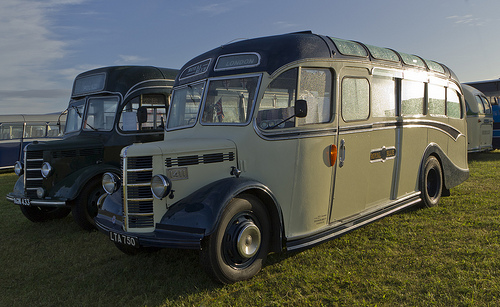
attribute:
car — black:
[45, 61, 266, 211]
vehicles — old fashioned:
[7, 32, 491, 272]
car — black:
[5, 65, 181, 232]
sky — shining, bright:
[0, 0, 498, 67]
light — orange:
[329, 142, 340, 166]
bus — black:
[5, 60, 176, 227]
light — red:
[333, 143, 338, 164]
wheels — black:
[191, 187, 351, 271]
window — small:
[198, 72, 260, 126]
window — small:
[161, 78, 206, 131]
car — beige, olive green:
[100, 27, 469, 280]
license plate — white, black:
[104, 228, 141, 250]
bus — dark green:
[6, 63, 294, 224]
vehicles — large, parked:
[94, 31, 472, 286]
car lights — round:
[97, 167, 177, 196]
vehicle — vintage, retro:
[93, 30, 469, 283]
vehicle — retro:
[6, 63, 181, 228]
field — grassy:
[300, 235, 498, 294]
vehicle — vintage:
[137, 60, 463, 240]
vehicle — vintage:
[139, 51, 449, 215]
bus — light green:
[179, 67, 453, 216]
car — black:
[10, 42, 243, 240]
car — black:
[15, 70, 215, 229]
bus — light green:
[90, 34, 480, 277]